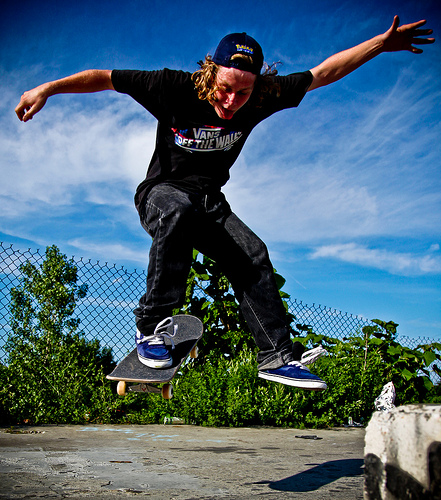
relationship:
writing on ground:
[80, 421, 235, 449] [0, 419, 364, 495]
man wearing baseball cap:
[10, 11, 433, 406] [204, 27, 267, 74]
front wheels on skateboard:
[114, 377, 175, 404] [100, 304, 210, 412]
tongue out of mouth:
[216, 106, 236, 120] [215, 101, 237, 119]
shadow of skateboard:
[256, 447, 361, 498] [97, 314, 214, 400]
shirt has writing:
[102, 60, 311, 201] [169, 124, 247, 156]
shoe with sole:
[134, 328, 173, 367] [137, 353, 173, 367]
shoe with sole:
[258, 361, 327, 389] [257, 371, 325, 389]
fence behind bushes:
[1, 243, 434, 421] [4, 246, 126, 426]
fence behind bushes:
[1, 243, 434, 421] [118, 243, 329, 426]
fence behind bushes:
[1, 243, 434, 421] [301, 318, 437, 426]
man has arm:
[14, 15, 435, 392] [264, 12, 438, 122]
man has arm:
[14, 15, 435, 392] [4, 60, 189, 126]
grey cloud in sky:
[284, 185, 308, 205] [2, 0, 414, 363]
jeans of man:
[131, 181, 311, 364] [14, 15, 435, 392]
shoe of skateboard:
[259, 357, 327, 392] [13, 10, 438, 387]